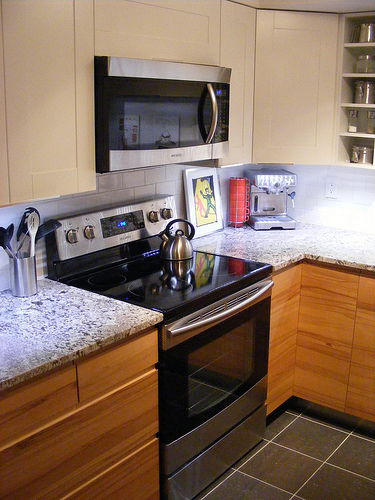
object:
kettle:
[158, 214, 198, 264]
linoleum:
[186, 416, 374, 500]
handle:
[170, 282, 274, 344]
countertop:
[0, 210, 301, 385]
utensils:
[2, 207, 52, 258]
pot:
[8, 251, 37, 298]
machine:
[245, 168, 301, 233]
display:
[98, 211, 145, 241]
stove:
[46, 194, 273, 497]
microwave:
[93, 55, 233, 164]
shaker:
[366, 110, 373, 136]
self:
[340, 131, 373, 144]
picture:
[183, 164, 228, 238]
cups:
[229, 176, 255, 229]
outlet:
[323, 180, 336, 198]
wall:
[1, 163, 250, 291]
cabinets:
[1, 1, 374, 207]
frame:
[181, 164, 223, 242]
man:
[195, 180, 216, 226]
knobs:
[67, 205, 175, 246]